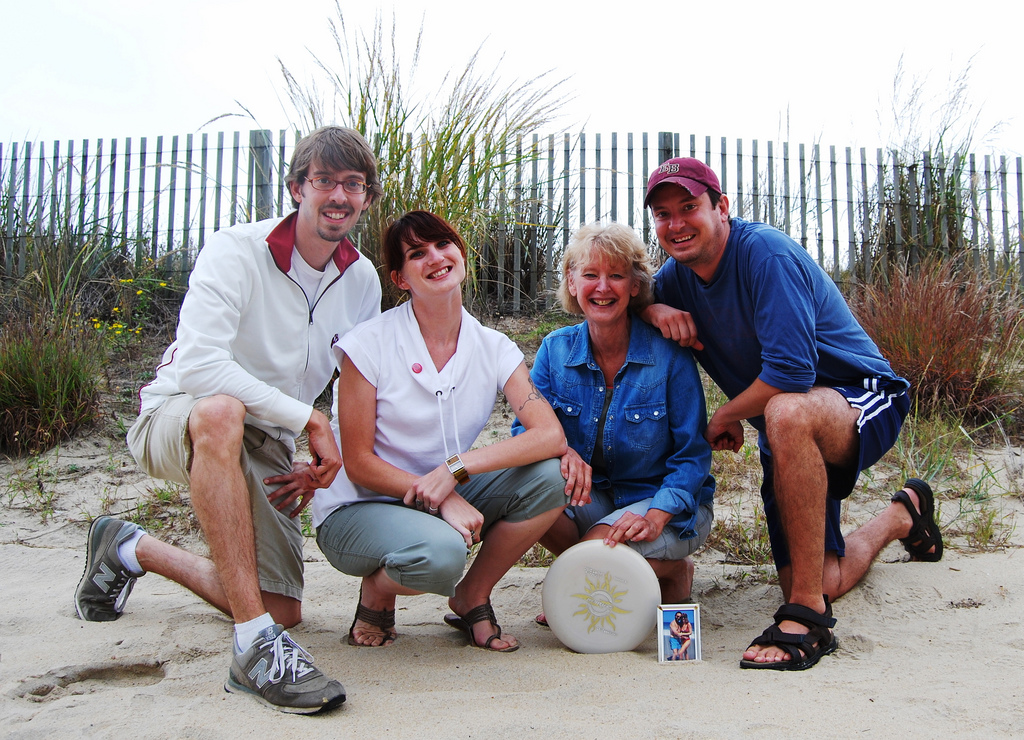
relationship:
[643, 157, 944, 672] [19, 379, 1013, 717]
man on beach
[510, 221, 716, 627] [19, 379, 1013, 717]
person on beach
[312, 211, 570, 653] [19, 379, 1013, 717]
person on beach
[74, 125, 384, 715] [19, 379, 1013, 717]
man on beach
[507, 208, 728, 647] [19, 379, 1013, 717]
person on beach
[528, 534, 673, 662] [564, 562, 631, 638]
frisbee with design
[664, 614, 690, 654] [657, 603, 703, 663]
picture in cap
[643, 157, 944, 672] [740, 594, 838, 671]
man wearing brown shoe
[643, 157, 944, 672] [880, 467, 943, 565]
man wearing sandal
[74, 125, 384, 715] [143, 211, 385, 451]
man in jacket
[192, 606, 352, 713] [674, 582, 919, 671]
silver n on brown shoe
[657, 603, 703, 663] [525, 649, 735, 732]
cap on ground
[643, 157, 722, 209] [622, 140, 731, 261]
hat on head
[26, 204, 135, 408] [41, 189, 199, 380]
flowers in trees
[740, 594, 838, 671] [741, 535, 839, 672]
brown shoe on feet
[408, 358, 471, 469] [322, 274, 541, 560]
strings from shirt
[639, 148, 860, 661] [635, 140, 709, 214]
man wearing hat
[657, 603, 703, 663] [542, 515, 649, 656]
cap next to frisbee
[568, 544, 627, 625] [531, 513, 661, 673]
sun graphic onto frisbee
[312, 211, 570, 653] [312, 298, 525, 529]
person wearing shirt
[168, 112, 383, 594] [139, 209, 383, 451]
man wearing jacket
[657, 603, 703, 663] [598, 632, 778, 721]
cap on sand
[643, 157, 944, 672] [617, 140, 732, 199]
man in hat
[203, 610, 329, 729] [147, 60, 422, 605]
foot on person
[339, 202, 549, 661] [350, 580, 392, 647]
person has a foot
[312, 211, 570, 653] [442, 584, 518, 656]
person has a foot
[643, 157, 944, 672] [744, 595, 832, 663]
man has a feet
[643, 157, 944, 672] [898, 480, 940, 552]
man has a foot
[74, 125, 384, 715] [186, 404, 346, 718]
man has a leg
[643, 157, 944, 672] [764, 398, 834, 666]
man has a leg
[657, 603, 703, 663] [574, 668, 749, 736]
cap on ground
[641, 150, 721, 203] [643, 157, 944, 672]
hat on man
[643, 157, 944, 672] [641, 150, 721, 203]
man has on a hat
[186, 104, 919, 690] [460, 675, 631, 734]
people are kneeling in sand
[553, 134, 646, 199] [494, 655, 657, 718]
fence behind sand